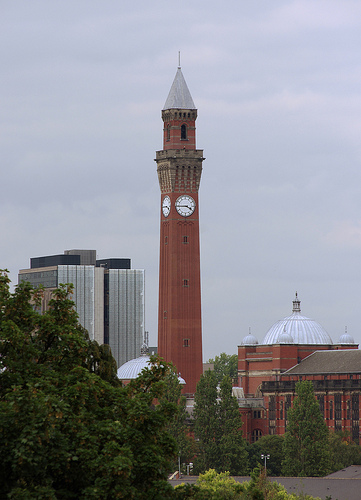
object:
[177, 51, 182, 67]
pole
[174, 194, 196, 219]
clock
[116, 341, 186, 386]
dome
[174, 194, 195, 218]
screen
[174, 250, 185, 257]
brick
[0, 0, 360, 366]
thick clouds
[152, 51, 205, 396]
building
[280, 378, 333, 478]
trees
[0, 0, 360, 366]
sky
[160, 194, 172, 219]
clock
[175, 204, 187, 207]
hand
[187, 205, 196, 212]
hand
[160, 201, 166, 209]
hand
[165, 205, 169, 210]
hand